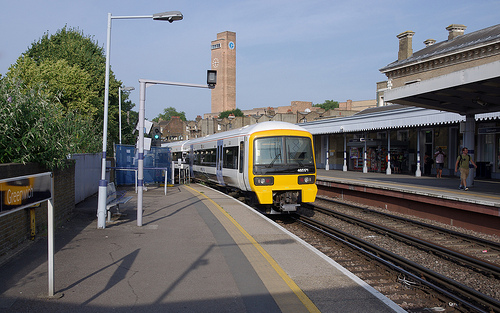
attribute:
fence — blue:
[130, 142, 171, 197]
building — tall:
[206, 28, 244, 110]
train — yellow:
[160, 118, 322, 220]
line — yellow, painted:
[182, 183, 319, 311]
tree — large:
[31, 31, 98, 142]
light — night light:
[149, 126, 161, 148]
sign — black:
[3, 170, 54, 212]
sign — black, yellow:
[3, 157, 55, 227]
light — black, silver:
[254, 174, 275, 186]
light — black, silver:
[296, 173, 315, 184]